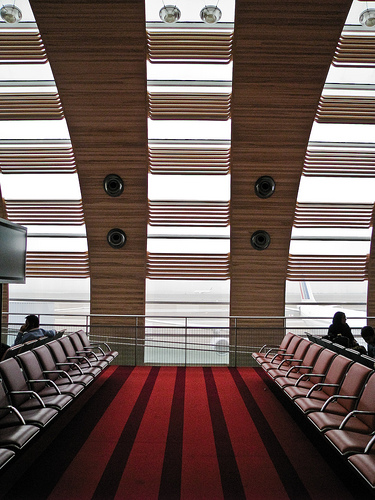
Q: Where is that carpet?
A: The carpet is on the floor.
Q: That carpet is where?
A: The carpet is on the floor.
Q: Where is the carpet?
A: The carpet is on the floor.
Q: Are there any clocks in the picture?
A: No, there are no clocks.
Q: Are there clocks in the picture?
A: No, there are no clocks.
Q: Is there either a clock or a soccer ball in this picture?
A: No, there are no clocks or soccer balls.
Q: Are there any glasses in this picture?
A: No, there are no glasses.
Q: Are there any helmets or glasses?
A: No, there are no glasses or helmets.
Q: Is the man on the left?
A: Yes, the man is on the left of the image.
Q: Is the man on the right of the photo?
A: No, the man is on the left of the image.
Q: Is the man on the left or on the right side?
A: The man is on the left of the image.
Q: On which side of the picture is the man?
A: The man is on the left of the image.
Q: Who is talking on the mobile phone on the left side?
A: The man is talking on the cell phone.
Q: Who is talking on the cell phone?
A: The man is talking on the cell phone.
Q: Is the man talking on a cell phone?
A: Yes, the man is talking on a cell phone.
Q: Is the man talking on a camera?
A: No, the man is talking on a cell phone.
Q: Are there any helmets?
A: No, there are no helmets.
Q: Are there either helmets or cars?
A: No, there are no helmets or cars.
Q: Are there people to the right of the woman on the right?
A: Yes, there is a person to the right of the woman.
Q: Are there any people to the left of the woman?
A: No, the person is to the right of the woman.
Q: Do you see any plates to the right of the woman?
A: No, there is a person to the right of the woman.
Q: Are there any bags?
A: No, there are no bags.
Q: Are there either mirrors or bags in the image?
A: No, there are no bags or mirrors.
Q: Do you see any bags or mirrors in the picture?
A: No, there are no bags or mirrors.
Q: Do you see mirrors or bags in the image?
A: No, there are no bags or mirrors.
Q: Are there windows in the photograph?
A: Yes, there is a window.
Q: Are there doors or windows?
A: Yes, there is a window.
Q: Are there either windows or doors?
A: Yes, there is a window.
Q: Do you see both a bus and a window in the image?
A: No, there is a window but no buses.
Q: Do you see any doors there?
A: No, there are no doors.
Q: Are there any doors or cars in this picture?
A: No, there are no doors or cars.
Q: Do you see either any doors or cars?
A: No, there are no doors or cars.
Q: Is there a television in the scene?
A: Yes, there is a television.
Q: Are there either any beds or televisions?
A: Yes, there is a television.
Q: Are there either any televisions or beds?
A: Yes, there is a television.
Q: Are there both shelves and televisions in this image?
A: No, there is a television but no shelves.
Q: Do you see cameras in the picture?
A: No, there are no cameras.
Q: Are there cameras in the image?
A: No, there are no cameras.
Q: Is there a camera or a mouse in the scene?
A: No, there are no cameras or computer mice.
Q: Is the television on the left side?
A: Yes, the television is on the left of the image.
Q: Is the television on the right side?
A: No, the television is on the left of the image.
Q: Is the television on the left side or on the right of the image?
A: The television is on the left of the image.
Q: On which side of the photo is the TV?
A: The TV is on the left of the image.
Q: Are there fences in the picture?
A: Yes, there is a fence.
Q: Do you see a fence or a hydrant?
A: Yes, there is a fence.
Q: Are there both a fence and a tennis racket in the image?
A: No, there is a fence but no rackets.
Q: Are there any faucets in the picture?
A: No, there are no faucets.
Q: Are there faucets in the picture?
A: No, there are no faucets.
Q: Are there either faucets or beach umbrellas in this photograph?
A: No, there are no faucets or beach umbrellas.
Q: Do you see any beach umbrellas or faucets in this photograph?
A: No, there are no faucets or beach umbrellas.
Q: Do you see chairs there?
A: Yes, there is a chair.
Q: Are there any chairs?
A: Yes, there is a chair.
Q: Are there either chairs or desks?
A: Yes, there is a chair.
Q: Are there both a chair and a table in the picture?
A: No, there is a chair but no tables.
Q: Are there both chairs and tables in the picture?
A: No, there is a chair but no tables.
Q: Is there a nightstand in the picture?
A: No, there are no nightstands.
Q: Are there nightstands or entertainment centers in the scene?
A: No, there are no nightstands or entertainment centers.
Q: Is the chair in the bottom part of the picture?
A: Yes, the chair is in the bottom of the image.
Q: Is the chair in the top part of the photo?
A: No, the chair is in the bottom of the image.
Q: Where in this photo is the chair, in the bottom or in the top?
A: The chair is in the bottom of the image.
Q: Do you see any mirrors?
A: No, there are no mirrors.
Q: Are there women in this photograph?
A: Yes, there is a woman.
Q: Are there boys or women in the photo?
A: Yes, there is a woman.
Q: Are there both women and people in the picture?
A: Yes, there are both a woman and people.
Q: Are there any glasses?
A: No, there are no glasses.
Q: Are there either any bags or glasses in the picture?
A: No, there are no glasses or bags.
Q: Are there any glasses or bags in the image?
A: No, there are no glasses or bags.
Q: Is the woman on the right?
A: Yes, the woman is on the right of the image.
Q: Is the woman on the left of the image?
A: No, the woman is on the right of the image.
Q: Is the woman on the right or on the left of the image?
A: The woman is on the right of the image.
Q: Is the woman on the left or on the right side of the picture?
A: The woman is on the right of the image.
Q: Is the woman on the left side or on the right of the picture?
A: The woman is on the right of the image.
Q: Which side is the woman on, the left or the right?
A: The woman is on the right of the image.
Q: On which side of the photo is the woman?
A: The woman is on the right of the image.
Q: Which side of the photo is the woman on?
A: The woman is on the right of the image.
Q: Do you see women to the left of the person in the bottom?
A: Yes, there is a woman to the left of the person.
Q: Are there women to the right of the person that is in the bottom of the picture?
A: No, the woman is to the left of the person.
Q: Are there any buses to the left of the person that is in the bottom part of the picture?
A: No, there is a woman to the left of the person.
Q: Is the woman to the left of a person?
A: Yes, the woman is to the left of a person.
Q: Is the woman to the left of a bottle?
A: No, the woman is to the left of a person.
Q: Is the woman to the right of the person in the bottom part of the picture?
A: No, the woman is to the left of the person.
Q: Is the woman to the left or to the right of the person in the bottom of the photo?
A: The woman is to the left of the person.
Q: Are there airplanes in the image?
A: Yes, there is an airplane.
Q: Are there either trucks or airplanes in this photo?
A: Yes, there is an airplane.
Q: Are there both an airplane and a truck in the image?
A: No, there is an airplane but no trucks.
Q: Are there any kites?
A: No, there are no kites.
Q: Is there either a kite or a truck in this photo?
A: No, there are no kites or trucks.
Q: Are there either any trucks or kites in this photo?
A: No, there are no kites or trucks.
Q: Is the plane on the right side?
A: Yes, the plane is on the right of the image.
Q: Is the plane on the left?
A: No, the plane is on the right of the image.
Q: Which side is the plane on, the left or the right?
A: The plane is on the right of the image.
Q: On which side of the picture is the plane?
A: The plane is on the right of the image.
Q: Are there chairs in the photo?
A: Yes, there is a chair.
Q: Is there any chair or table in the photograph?
A: Yes, there is a chair.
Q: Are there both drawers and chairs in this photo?
A: No, there is a chair but no drawers.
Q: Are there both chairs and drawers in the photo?
A: No, there is a chair but no drawers.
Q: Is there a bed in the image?
A: No, there are no beds.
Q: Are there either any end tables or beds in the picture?
A: No, there are no beds or end tables.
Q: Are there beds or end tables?
A: No, there are no beds or end tables.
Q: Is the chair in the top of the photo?
A: No, the chair is in the bottom of the image.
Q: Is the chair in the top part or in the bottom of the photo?
A: The chair is in the bottom of the image.